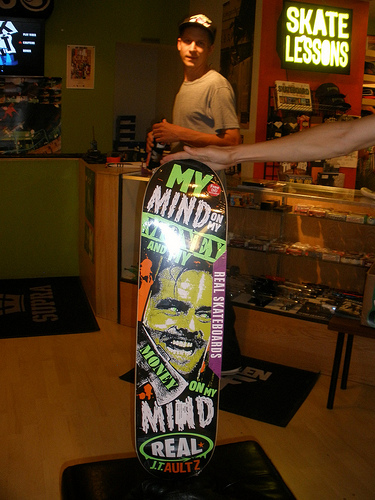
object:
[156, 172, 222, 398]
board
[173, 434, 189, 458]
letter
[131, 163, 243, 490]
skateboard deck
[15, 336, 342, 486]
deck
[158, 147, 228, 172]
hand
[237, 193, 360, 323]
case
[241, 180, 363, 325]
counter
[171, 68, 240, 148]
shirt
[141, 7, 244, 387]
man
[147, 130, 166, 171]
bottle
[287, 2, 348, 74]
sign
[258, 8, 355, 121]
wall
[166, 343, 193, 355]
teeth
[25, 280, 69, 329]
letters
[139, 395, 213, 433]
word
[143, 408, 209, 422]
text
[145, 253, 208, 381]
image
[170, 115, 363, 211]
man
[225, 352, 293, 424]
rug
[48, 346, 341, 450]
floor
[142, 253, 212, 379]
jack-nicholson's face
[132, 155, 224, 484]
skateboard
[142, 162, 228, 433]
words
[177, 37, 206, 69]
face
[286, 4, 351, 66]
skate lessons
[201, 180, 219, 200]
sticker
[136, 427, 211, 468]
sticker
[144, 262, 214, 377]
face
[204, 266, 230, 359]
text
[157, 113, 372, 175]
arm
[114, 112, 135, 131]
shelf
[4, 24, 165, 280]
back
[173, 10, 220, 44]
cap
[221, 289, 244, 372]
pants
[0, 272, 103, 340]
mat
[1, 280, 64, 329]
logo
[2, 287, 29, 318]
crown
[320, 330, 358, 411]
legs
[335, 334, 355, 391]
leg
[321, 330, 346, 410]
leg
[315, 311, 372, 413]
bench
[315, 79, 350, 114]
caps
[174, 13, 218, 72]
head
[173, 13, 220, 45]
hat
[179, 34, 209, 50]
eyes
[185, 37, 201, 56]
nose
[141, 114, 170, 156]
hands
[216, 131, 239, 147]
elbow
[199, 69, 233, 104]
shoulder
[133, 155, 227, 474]
snowboard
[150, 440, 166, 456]
letter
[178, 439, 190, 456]
letter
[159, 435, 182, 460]
letter